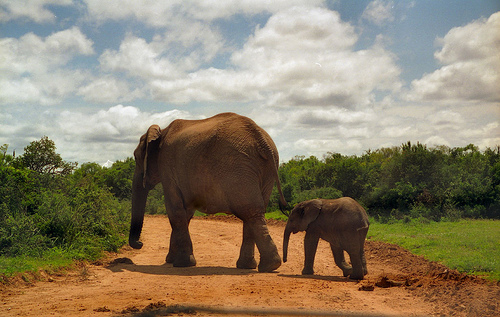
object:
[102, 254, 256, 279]
shadows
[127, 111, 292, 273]
elephant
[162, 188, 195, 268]
leg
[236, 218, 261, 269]
leg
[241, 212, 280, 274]
leg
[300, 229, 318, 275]
leg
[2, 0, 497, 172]
clouds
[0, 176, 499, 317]
ground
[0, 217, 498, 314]
trail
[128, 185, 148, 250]
trunk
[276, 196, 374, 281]
baby elephant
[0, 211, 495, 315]
dirt road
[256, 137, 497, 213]
tree line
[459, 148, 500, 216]
bushes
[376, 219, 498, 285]
grassy field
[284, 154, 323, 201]
trees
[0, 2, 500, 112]
blue sky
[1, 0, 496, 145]
sky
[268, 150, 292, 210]
elephant's tail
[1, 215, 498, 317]
road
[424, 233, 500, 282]
grass